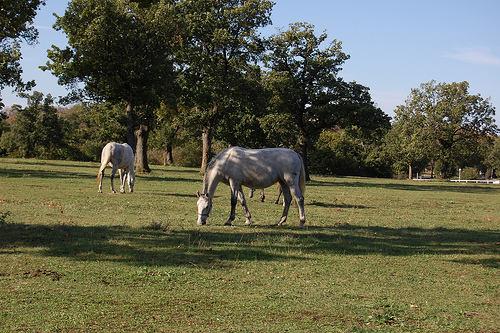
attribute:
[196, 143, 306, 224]
horse — white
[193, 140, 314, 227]
horse — white 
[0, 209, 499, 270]
shadow — tree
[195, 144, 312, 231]
horse — white, grazing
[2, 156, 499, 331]
grass — green, light green, mowed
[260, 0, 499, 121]
sky — blue, cloudy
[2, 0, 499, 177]
trees — leafy, green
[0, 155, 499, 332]
pasture — green, grassy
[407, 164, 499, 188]
fence — white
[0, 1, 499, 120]
sky — clear, blue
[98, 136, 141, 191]
horse — white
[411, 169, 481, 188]
fences — white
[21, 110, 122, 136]
leaves — brown 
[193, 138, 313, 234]
horse — white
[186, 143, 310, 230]
horse — white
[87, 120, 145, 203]
horse — white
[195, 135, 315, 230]
horse — white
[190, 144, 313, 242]
horse — white 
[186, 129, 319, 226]
horse — white 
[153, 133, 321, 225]
horse — white 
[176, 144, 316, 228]
horse — white 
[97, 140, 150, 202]
horse — grazing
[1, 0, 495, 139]
sky — blue  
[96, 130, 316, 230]
horses — white 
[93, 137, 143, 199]
horse — white 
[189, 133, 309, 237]
horse — white 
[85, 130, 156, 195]
horse — white 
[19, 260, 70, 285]
manure — horse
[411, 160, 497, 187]
fence — round, white, wood